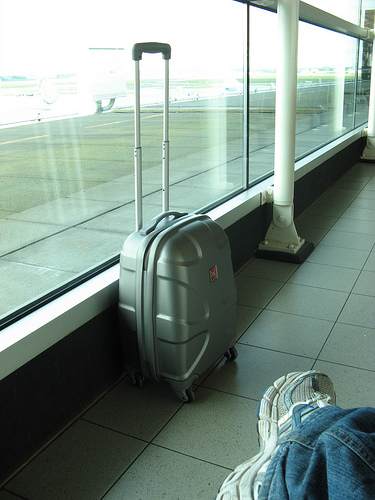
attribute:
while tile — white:
[272, 279, 348, 326]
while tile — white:
[329, 199, 368, 237]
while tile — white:
[146, 403, 239, 462]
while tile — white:
[319, 240, 365, 290]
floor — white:
[11, 309, 341, 498]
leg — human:
[305, 406, 374, 498]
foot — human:
[215, 369, 334, 499]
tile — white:
[272, 284, 298, 316]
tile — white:
[214, 269, 286, 311]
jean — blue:
[243, 358, 360, 483]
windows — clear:
[0, 1, 372, 336]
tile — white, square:
[100, 441, 234, 497]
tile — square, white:
[2, 418, 150, 497]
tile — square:
[148, 385, 264, 470]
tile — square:
[80, 371, 187, 443]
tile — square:
[199, 342, 317, 400]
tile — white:
[186, 112, 239, 183]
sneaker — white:
[204, 367, 342, 499]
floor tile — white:
[234, 297, 262, 340]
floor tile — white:
[265, 286, 346, 320]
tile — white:
[77, 370, 200, 443]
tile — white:
[191, 329, 321, 417]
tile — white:
[233, 299, 346, 360]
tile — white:
[259, 269, 359, 323]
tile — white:
[279, 246, 369, 302]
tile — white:
[298, 230, 373, 280]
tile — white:
[320, 187, 366, 220]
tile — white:
[100, 438, 241, 498]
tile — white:
[318, 321, 373, 370]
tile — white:
[243, 306, 338, 366]